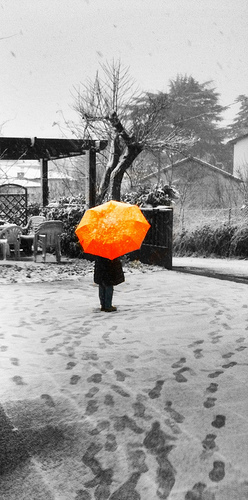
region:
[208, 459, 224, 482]
A footprint in the snow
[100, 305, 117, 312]
The person is wearing shoes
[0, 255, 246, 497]
Snow on the ground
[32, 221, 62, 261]
A chair on the snow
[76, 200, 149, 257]
The umbrella is orange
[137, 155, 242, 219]
A building behind the fence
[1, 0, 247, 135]
The sky above the person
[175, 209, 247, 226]
A fence by the bushes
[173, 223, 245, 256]
Bushes above the snow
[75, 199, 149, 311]
A person standing beneath an orange umbrella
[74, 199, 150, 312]
Person holding orange umbrella in snow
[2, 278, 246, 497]
Footprints on ground in the snow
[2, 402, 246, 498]
Dusting of snow on the pavement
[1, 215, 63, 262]
Plastic chairs stacked in the corner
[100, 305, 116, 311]
Brown boots on person's feet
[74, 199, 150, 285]
Person wearing long black coat under umbrella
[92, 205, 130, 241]
Snow on top of orange umbrella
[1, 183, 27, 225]
Trellis behind stacked chairs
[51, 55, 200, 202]
Tree and branches covered with snow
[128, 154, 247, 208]
House in the background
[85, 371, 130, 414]
Footprints in the snow.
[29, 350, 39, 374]
part of the snow.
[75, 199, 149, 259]
An orange umbrella.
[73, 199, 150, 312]
A person holding an umbrella.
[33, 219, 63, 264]
A couple of stacked chairs.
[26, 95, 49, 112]
Part of the sky.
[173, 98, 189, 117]
Part of a tree.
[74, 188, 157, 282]
a person holding a umbrella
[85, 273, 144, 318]
the legs of a person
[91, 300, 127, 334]
the feet of a person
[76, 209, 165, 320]
a person standing in snow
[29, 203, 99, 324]
a chair near a person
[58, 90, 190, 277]
a person near a tree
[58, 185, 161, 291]
a big orange umbrella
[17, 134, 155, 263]
a chair near a tree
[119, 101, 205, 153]
a tree with no leaves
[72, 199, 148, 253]
this is an umbrella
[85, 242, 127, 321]
this is a person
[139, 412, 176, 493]
these are foot prints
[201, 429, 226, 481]
these are foot prints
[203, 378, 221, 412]
these are foot prints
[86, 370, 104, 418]
these are foot prints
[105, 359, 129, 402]
these are foot prints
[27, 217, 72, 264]
this is a chair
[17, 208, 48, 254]
this is a chair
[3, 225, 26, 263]
this is a chair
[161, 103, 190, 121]
leaves on the bush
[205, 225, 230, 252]
leaves on the bush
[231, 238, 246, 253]
leaves on the bush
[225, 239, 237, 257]
leaves on the bush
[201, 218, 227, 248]
leaves on the bush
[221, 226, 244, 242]
leaves on the bush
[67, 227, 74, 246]
leaves on the bush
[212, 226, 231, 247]
leaves on the bush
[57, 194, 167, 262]
an orange opened umbrella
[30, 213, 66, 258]
a stack of outside chairs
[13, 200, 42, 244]
a white chair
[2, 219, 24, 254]
a tall green tree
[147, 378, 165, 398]
a footprint in the snow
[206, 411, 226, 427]
a footprint in the snow